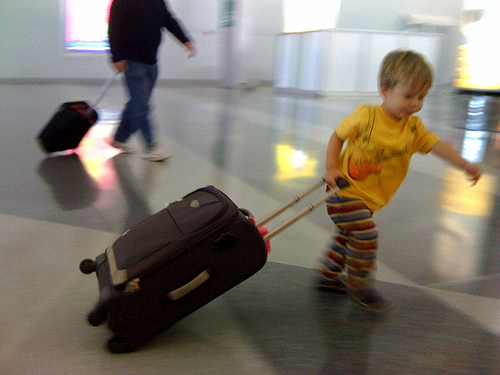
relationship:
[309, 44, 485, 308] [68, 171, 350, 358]
child dragging a suitcase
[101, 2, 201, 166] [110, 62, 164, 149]
adult in jeans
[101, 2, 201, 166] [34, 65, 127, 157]
adult pulling suitcase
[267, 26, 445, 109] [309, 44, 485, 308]
counters are behind child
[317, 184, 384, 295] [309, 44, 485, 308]
pants on child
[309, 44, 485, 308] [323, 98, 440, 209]
child wearing top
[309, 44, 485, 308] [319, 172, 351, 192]
child holding handle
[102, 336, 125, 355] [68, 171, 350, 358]
wheel on suitcase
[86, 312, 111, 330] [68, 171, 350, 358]
wheel on suitcase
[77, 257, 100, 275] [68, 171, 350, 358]
wheel on suitcase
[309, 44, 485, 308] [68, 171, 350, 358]
child has suitcase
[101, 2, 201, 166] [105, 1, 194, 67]
adult wearing top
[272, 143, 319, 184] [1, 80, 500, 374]
area on floor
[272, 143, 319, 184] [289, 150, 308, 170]
area has circle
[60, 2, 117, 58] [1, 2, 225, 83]
window on wall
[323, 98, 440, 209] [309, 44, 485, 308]
top on a child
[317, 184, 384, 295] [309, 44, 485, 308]
pants on a child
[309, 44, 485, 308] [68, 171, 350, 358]
child pulling suitcase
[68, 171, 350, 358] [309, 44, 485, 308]
suitcase pulled by child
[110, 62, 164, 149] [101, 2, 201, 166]
jeans on an adult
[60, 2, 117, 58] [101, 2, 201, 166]
window behind an adult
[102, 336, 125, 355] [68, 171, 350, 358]
wheel on a suitcase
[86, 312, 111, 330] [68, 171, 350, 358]
wheel on a suitcase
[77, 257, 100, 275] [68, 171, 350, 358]
wheel on a suitcase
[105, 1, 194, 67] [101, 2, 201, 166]
top on an adult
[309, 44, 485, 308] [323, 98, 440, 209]
child wearing a top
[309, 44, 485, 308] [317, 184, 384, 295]
child wears pants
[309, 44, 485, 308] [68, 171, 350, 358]
child dragging suitcase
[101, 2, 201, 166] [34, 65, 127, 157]
adult dragging suitcase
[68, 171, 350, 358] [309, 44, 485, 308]
suitcase being dragged by child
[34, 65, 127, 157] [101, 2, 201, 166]
suitcase dragged by an adult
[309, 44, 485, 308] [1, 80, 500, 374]
child walking on floor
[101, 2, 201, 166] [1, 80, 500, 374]
adult walking on floor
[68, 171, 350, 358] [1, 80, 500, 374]
suitcase being dragged on floor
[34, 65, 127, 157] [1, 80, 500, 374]
suitcase being dragged on floor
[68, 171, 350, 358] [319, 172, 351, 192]
suitcase has handle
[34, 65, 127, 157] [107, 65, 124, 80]
suitcase has handle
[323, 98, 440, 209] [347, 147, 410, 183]
top has guitar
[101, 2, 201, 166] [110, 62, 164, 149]
adult with jeans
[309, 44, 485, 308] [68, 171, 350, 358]
child pulling a suitcase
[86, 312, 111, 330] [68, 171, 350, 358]
wheel of suitcase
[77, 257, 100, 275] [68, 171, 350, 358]
wheel of suitcase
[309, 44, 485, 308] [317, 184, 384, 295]
boy wearing pants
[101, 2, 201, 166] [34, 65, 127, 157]
adult pulling a suitcase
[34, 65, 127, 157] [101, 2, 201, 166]
suitcase pulled by adult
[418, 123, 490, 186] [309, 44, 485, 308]
left arm of child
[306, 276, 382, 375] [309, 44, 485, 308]
shadow of child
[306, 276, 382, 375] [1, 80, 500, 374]
shadow on floor